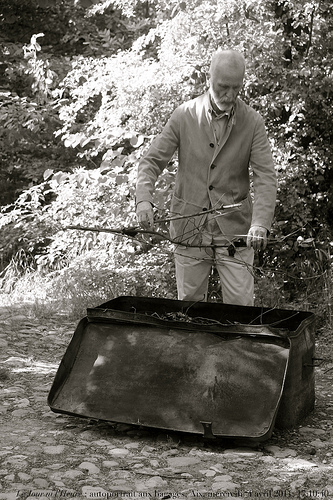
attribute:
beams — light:
[31, 65, 123, 247]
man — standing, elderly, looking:
[135, 48, 277, 306]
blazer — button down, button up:
[135, 94, 278, 246]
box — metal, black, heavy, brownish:
[47, 296, 314, 450]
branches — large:
[69, 223, 245, 255]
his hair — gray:
[208, 48, 246, 80]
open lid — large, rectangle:
[50, 321, 290, 444]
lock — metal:
[201, 418, 214, 443]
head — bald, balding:
[207, 48, 246, 110]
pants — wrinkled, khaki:
[171, 244, 255, 308]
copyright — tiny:
[15, 486, 332, 499]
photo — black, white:
[0, 2, 332, 500]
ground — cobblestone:
[2, 441, 333, 499]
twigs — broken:
[103, 303, 300, 333]